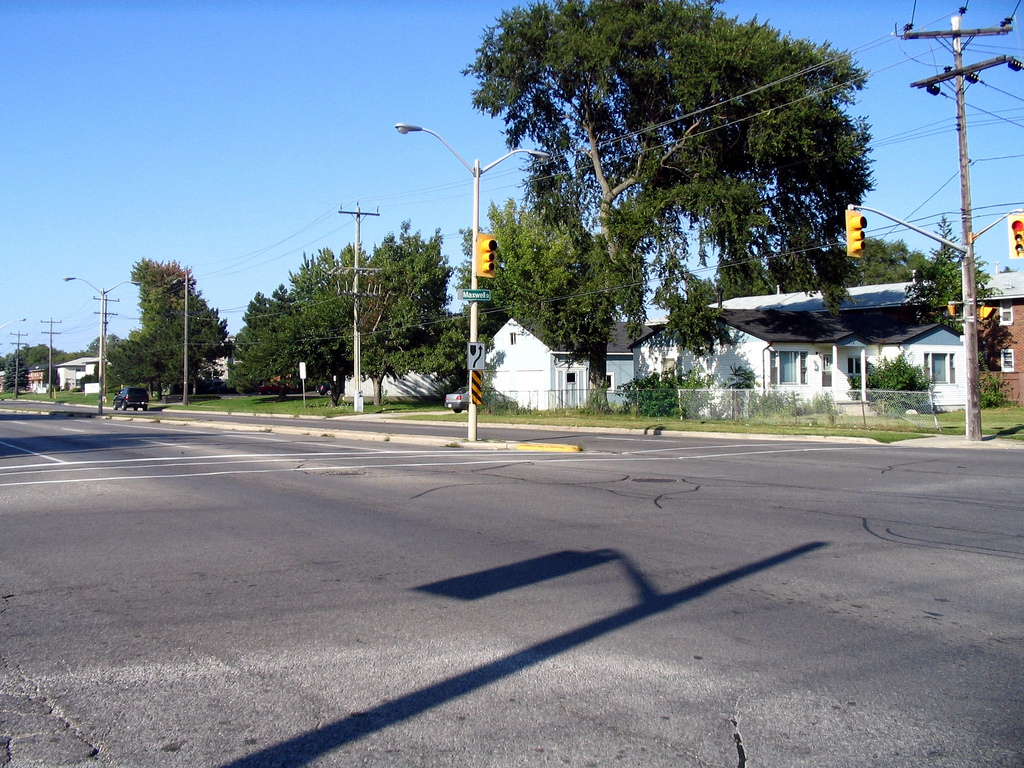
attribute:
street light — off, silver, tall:
[395, 122, 551, 439]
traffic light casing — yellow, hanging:
[473, 231, 497, 277]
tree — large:
[456, 0, 876, 413]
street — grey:
[1, 397, 1022, 765]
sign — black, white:
[468, 340, 485, 370]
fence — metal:
[548, 384, 951, 431]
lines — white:
[0, 418, 876, 487]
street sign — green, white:
[459, 290, 493, 300]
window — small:
[1000, 350, 1016, 371]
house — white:
[625, 302, 967, 417]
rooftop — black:
[628, 302, 990, 356]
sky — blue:
[0, 0, 1021, 355]